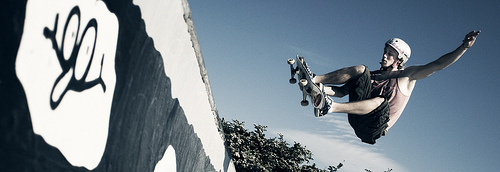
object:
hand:
[461, 29, 481, 48]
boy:
[286, 30, 481, 146]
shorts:
[345, 66, 388, 144]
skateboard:
[286, 54, 324, 109]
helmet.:
[383, 38, 412, 69]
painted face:
[13, 0, 120, 170]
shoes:
[289, 54, 316, 85]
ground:
[366, 17, 435, 87]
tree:
[213, 114, 346, 172]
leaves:
[244, 141, 282, 162]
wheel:
[285, 58, 298, 64]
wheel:
[287, 76, 299, 84]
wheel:
[296, 78, 310, 87]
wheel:
[300, 100, 309, 106]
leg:
[336, 96, 391, 138]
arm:
[404, 46, 468, 91]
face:
[380, 48, 396, 67]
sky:
[198, 7, 494, 170]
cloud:
[258, 124, 407, 169]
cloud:
[321, 110, 365, 145]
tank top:
[369, 66, 412, 133]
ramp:
[0, 0, 238, 172]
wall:
[0, 0, 236, 172]